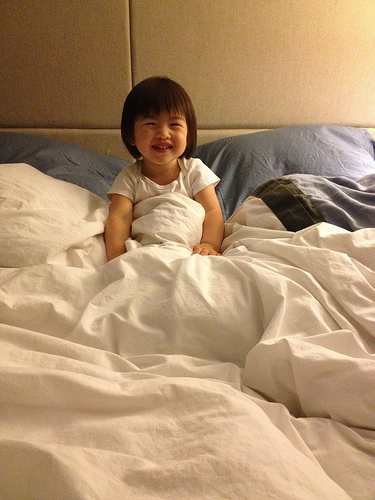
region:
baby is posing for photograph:
[97, 75, 225, 285]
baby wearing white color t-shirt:
[106, 164, 216, 222]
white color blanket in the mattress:
[5, 187, 318, 499]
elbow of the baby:
[192, 198, 233, 230]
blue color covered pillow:
[217, 129, 370, 204]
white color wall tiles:
[180, 6, 336, 99]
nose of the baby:
[153, 128, 174, 142]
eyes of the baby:
[142, 112, 189, 132]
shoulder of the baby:
[179, 159, 213, 173]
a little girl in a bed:
[110, 96, 225, 293]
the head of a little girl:
[115, 77, 195, 174]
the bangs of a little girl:
[125, 90, 187, 117]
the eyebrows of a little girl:
[139, 110, 188, 120]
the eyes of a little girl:
[142, 117, 183, 132]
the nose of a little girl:
[153, 122, 168, 141]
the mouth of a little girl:
[150, 133, 175, 152]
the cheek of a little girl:
[141, 133, 162, 142]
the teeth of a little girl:
[153, 143, 171, 152]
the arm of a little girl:
[98, 190, 131, 253]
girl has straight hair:
[113, 63, 231, 183]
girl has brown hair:
[112, 71, 201, 159]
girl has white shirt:
[89, 112, 235, 259]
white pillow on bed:
[3, 149, 100, 279]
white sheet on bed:
[9, 247, 337, 497]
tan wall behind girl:
[228, 14, 351, 111]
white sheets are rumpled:
[84, 222, 309, 460]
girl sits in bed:
[87, 77, 242, 283]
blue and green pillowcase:
[266, 178, 371, 250]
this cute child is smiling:
[102, 72, 226, 268]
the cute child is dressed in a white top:
[105, 155, 223, 202]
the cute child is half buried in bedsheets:
[2, 67, 343, 312]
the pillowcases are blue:
[1, 120, 372, 222]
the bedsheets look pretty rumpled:
[0, 159, 374, 498]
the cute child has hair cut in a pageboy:
[117, 74, 200, 161]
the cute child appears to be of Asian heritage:
[115, 71, 204, 162]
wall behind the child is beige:
[1, 2, 372, 126]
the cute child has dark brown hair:
[118, 72, 201, 162]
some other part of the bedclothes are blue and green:
[247, 167, 373, 238]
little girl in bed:
[101, 73, 224, 262]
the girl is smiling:
[118, 75, 195, 167]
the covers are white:
[0, 160, 373, 498]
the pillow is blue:
[199, 122, 374, 220]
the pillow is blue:
[0, 127, 129, 203]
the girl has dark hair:
[116, 74, 197, 160]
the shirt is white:
[106, 157, 219, 203]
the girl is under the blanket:
[101, 72, 226, 262]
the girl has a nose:
[153, 123, 170, 140]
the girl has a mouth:
[148, 138, 175, 154]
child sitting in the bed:
[103, 70, 226, 255]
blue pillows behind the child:
[0, 109, 370, 226]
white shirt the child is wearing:
[109, 155, 216, 210]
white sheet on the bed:
[0, 162, 369, 495]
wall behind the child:
[0, 5, 350, 159]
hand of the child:
[191, 243, 220, 260]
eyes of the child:
[141, 119, 183, 130]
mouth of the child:
[147, 139, 172, 154]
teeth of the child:
[153, 140, 169, 149]